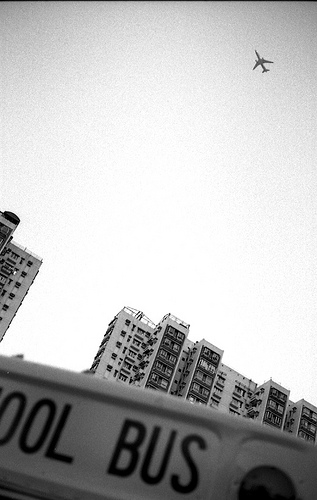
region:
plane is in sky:
[238, 51, 275, 87]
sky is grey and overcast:
[133, 60, 269, 196]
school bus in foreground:
[5, 366, 272, 494]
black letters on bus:
[3, 380, 261, 495]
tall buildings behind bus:
[3, 226, 312, 417]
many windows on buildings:
[123, 317, 315, 418]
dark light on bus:
[232, 459, 289, 497]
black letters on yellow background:
[0, 383, 286, 493]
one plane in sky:
[238, 46, 269, 94]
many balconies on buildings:
[114, 324, 313, 462]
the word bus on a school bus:
[113, 416, 197, 490]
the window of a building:
[168, 326, 174, 333]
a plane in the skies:
[249, 48, 273, 74]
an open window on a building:
[273, 390, 277, 395]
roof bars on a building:
[126, 305, 137, 310]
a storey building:
[113, 311, 193, 372]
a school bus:
[49, 372, 128, 420]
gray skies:
[96, 112, 226, 195]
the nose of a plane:
[252, 49, 258, 53]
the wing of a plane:
[265, 58, 275, 65]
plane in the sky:
[232, 39, 279, 87]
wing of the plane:
[262, 52, 279, 70]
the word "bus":
[93, 410, 220, 491]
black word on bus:
[102, 414, 222, 491]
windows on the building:
[134, 322, 190, 381]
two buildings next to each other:
[1, 260, 178, 327]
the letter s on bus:
[165, 427, 217, 498]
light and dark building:
[109, 326, 199, 368]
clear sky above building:
[21, 20, 93, 92]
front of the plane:
[243, 43, 267, 60]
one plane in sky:
[250, 43, 271, 78]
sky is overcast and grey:
[154, 148, 272, 306]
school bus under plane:
[6, 370, 214, 481]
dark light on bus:
[246, 444, 283, 492]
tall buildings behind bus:
[106, 308, 287, 432]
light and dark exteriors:
[122, 295, 306, 447]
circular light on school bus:
[236, 463, 300, 499]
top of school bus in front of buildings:
[0, 349, 316, 499]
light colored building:
[84, 304, 315, 448]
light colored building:
[0, 204, 45, 353]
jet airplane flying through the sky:
[249, 48, 275, 74]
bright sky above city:
[0, 0, 316, 409]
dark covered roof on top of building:
[1, 207, 25, 226]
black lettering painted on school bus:
[0, 381, 209, 494]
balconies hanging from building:
[245, 388, 263, 421]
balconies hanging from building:
[132, 318, 163, 381]